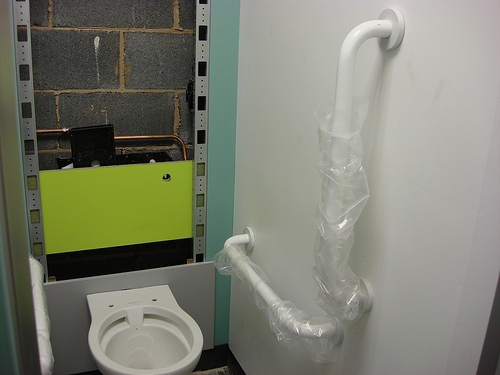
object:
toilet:
[85, 283, 205, 374]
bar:
[322, 8, 404, 315]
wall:
[408, 60, 497, 212]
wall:
[32, 1, 196, 118]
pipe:
[36, 128, 69, 133]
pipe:
[114, 135, 188, 161]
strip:
[198, 347, 229, 372]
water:
[129, 344, 157, 367]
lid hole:
[108, 304, 114, 308]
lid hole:
[152, 298, 158, 302]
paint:
[91, 36, 100, 80]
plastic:
[310, 108, 369, 323]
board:
[207, 1, 241, 347]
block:
[35, 28, 120, 90]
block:
[125, 33, 192, 89]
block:
[58, 93, 173, 148]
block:
[51, 0, 175, 29]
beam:
[10, 1, 48, 283]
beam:
[193, 1, 211, 263]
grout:
[30, 26, 196, 34]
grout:
[36, 88, 185, 92]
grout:
[119, 31, 125, 88]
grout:
[174, 92, 180, 144]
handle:
[224, 226, 344, 348]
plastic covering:
[209, 243, 335, 366]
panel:
[32, 260, 217, 374]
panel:
[68, 73, 133, 123]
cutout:
[16, 24, 28, 42]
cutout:
[19, 64, 30, 81]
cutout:
[21, 102, 32, 118]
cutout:
[199, 25, 208, 41]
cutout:
[198, 62, 207, 76]